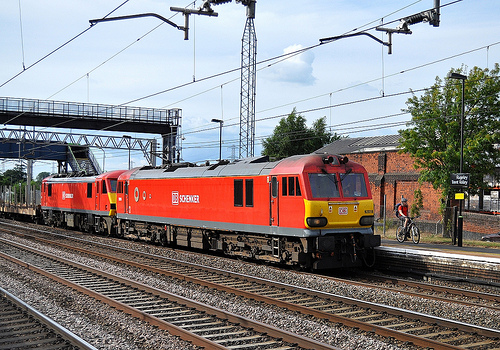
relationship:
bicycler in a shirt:
[394, 198, 412, 241] [400, 210, 407, 216]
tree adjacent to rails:
[402, 64, 492, 211] [0, 213, 499, 348]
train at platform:
[30, 151, 381, 273] [373, 233, 498, 283]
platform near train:
[382, 236, 496, 273] [30, 151, 381, 273]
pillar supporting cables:
[214, 32, 306, 137] [2, 0, 499, 162]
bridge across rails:
[4, 95, 198, 160] [0, 213, 499, 348]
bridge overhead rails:
[4, 95, 198, 160] [0, 213, 499, 348]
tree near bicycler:
[395, 62, 499, 238] [394, 198, 412, 241]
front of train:
[303, 200, 375, 227] [30, 151, 381, 273]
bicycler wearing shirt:
[394, 198, 412, 241] [396, 205, 406, 217]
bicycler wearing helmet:
[394, 198, 412, 241] [397, 197, 409, 203]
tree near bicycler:
[404, 61, 494, 244] [391, 196, 421, 242]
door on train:
[267, 174, 278, 226] [30, 151, 381, 273]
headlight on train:
[305, 215, 327, 226] [0, 151, 381, 265]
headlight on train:
[358, 214, 374, 225] [0, 151, 381, 265]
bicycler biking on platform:
[394, 198, 412, 241] [373, 230, 499, 287]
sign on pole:
[440, 168, 472, 250] [458, 76, 465, 246]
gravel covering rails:
[52, 293, 144, 348] [5, 220, 498, 349]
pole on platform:
[438, 71, 465, 252] [371, 221, 497, 286]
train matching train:
[130, 158, 397, 268] [39, 166, 134, 229]